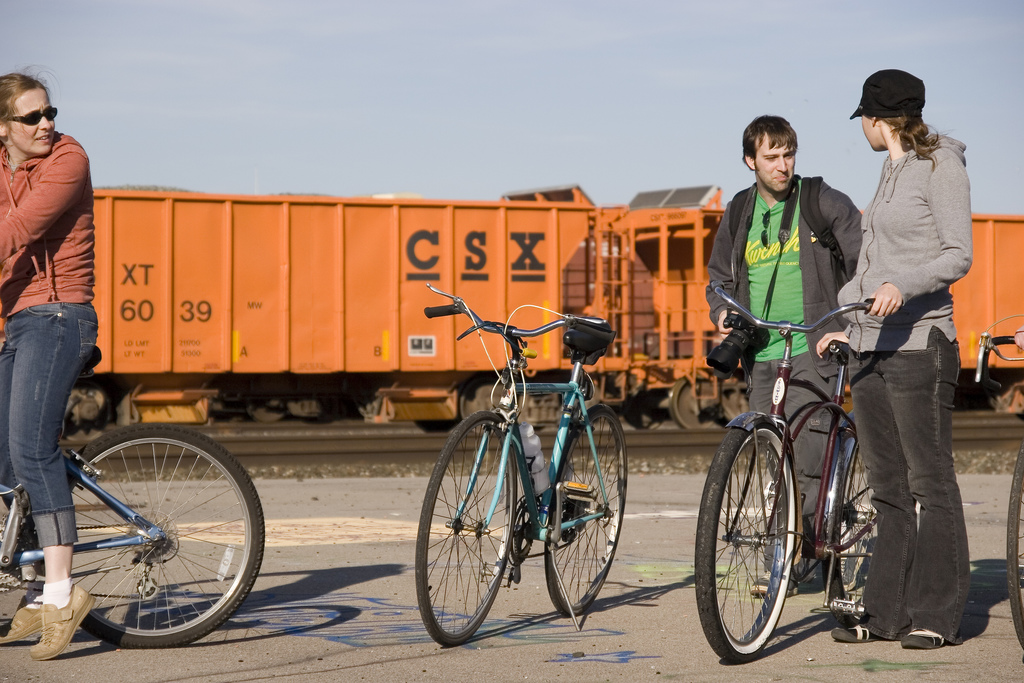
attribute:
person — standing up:
[705, 111, 865, 596]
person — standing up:
[810, 65, 975, 650]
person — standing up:
[0, 67, 102, 656]